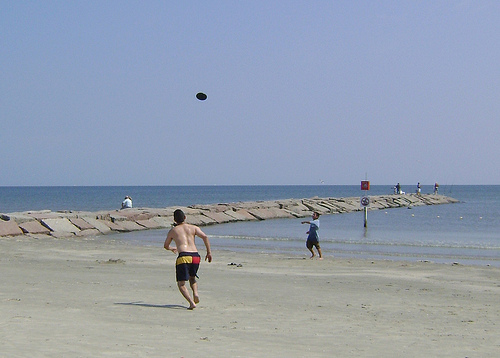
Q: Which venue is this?
A: This is a beach.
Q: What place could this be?
A: It is a beach.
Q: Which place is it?
A: It is a beach.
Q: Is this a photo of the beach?
A: Yes, it is showing the beach.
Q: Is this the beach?
A: Yes, it is the beach.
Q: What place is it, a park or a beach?
A: It is a beach.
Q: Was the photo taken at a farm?
A: No, the picture was taken in a beach.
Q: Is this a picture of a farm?
A: No, the picture is showing a beach.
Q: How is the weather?
A: It is clear.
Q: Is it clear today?
A: Yes, it is clear.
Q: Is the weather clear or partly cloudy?
A: It is clear.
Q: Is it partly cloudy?
A: No, it is clear.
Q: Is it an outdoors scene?
A: Yes, it is outdoors.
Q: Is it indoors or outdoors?
A: It is outdoors.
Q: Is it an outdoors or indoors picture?
A: It is outdoors.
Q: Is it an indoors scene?
A: No, it is outdoors.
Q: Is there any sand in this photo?
A: Yes, there is sand.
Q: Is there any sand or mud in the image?
A: Yes, there is sand.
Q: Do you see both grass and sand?
A: No, there is sand but no grass.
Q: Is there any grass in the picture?
A: No, there is no grass.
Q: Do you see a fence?
A: No, there are no fences.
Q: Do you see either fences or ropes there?
A: No, there are no fences or ropes.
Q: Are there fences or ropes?
A: No, there are no fences or ropes.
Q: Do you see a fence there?
A: No, there are no fences.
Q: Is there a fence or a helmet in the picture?
A: No, there are no fences or helmets.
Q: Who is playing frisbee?
A: The boy is playing frisbee.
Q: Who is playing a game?
A: The boy is playing a game.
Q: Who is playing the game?
A: The boy is playing a game.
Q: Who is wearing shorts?
A: The boy is wearing shorts.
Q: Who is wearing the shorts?
A: The boy is wearing shorts.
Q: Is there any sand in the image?
A: Yes, there is sand.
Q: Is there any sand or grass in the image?
A: Yes, there is sand.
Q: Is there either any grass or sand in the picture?
A: Yes, there is sand.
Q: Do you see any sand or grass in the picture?
A: Yes, there is sand.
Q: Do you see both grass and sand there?
A: No, there is sand but no grass.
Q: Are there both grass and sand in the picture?
A: No, there is sand but no grass.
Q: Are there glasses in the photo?
A: No, there are no glasses.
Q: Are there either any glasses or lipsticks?
A: No, there are no glasses or lipsticks.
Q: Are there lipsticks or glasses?
A: No, there are no glasses or lipsticks.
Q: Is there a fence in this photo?
A: No, there are no fences.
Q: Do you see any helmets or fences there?
A: No, there are no fences or helmets.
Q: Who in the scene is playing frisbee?
A: The boy is playing frisbee.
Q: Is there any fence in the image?
A: No, there are no fences.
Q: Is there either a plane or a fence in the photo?
A: No, there are no fences or airplanes.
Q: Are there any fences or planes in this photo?
A: No, there are no fences or planes.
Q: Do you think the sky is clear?
A: Yes, the sky is clear.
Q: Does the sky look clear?
A: Yes, the sky is clear.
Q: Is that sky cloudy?
A: No, the sky is clear.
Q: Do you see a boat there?
A: No, there are no boats.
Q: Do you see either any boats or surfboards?
A: No, there are no boats or surfboards.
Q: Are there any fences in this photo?
A: No, there are no fences.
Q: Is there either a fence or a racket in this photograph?
A: No, there are no fences or rackets.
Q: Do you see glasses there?
A: No, there are no glasses.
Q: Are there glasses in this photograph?
A: No, there are no glasses.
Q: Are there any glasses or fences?
A: No, there are no glasses or fences.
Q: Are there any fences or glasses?
A: No, there are no glasses or fences.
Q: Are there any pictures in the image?
A: No, there are no pictures.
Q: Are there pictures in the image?
A: No, there are no pictures.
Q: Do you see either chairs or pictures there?
A: No, there are no pictures or chairs.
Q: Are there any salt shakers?
A: No, there are no salt shakers.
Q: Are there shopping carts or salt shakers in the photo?
A: No, there are no salt shakers or shopping carts.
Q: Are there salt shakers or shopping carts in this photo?
A: No, there are no salt shakers or shopping carts.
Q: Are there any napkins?
A: No, there are no napkins.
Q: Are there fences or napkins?
A: No, there are no napkins or fences.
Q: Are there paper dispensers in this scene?
A: No, there are no paper dispensers.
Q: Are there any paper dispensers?
A: No, there are no paper dispensers.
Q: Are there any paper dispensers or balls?
A: No, there are no paper dispensers or balls.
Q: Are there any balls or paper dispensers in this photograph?
A: No, there are no paper dispensers or balls.